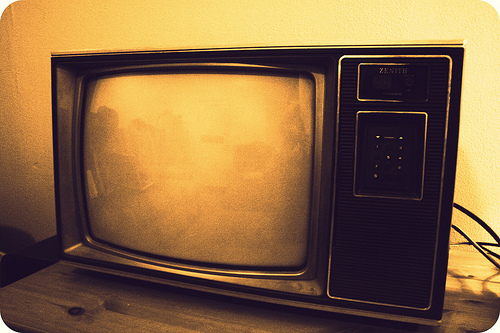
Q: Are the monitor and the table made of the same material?
A: No, the monitor is made of glass and the table is made of wood.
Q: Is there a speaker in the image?
A: Yes, there is a speaker.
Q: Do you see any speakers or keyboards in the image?
A: Yes, there is a speaker.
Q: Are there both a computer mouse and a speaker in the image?
A: No, there is a speaker but no computer mice.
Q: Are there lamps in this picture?
A: No, there are no lamps.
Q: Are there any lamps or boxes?
A: No, there are no lamps or boxes.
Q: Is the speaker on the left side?
A: No, the speaker is on the right of the image.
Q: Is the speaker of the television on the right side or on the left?
A: The speaker is on the right of the image.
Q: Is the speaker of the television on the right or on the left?
A: The speaker is on the right of the image.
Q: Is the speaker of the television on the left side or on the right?
A: The speaker is on the right of the image.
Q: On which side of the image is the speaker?
A: The speaker is on the right of the image.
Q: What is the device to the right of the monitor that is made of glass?
A: The device is a speaker.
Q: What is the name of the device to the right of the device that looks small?
A: The device is a speaker.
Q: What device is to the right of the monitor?
A: The device is a speaker.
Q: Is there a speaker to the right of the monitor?
A: Yes, there is a speaker to the right of the monitor.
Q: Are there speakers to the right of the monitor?
A: Yes, there is a speaker to the right of the monitor.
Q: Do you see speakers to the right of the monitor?
A: Yes, there is a speaker to the right of the monitor.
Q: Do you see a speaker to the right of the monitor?
A: Yes, there is a speaker to the right of the monitor.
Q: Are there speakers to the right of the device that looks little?
A: Yes, there is a speaker to the right of the monitor.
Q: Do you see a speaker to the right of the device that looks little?
A: Yes, there is a speaker to the right of the monitor.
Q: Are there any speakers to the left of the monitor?
A: No, the speaker is to the right of the monitor.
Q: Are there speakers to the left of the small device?
A: No, the speaker is to the right of the monitor.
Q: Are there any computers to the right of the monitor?
A: No, there is a speaker to the right of the monitor.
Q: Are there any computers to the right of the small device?
A: No, there is a speaker to the right of the monitor.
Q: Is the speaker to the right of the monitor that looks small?
A: Yes, the speaker is to the right of the monitor.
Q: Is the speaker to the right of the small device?
A: Yes, the speaker is to the right of the monitor.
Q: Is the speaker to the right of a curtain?
A: No, the speaker is to the right of the monitor.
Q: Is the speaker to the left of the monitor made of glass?
A: No, the speaker is to the right of the monitor.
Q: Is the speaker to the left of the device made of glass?
A: No, the speaker is to the right of the monitor.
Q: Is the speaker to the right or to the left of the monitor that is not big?
A: The speaker is to the right of the monitor.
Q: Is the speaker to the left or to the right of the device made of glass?
A: The speaker is to the right of the monitor.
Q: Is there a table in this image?
A: Yes, there is a table.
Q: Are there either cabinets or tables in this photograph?
A: Yes, there is a table.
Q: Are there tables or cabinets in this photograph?
A: Yes, there is a table.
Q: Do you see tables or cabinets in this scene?
A: Yes, there is a table.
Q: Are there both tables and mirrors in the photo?
A: No, there is a table but no mirrors.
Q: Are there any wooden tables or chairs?
A: Yes, there is a wood table.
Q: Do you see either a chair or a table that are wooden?
A: Yes, the table is wooden.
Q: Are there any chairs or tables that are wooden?
A: Yes, the table is wooden.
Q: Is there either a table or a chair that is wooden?
A: Yes, the table is wooden.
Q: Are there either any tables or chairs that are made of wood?
A: Yes, the table is made of wood.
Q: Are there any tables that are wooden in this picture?
A: Yes, there is a wood table.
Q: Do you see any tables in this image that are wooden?
A: Yes, there is a table that is wooden.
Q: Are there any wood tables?
A: Yes, there is a table that is made of wood.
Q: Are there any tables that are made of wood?
A: Yes, there is a table that is made of wood.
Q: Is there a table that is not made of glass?
A: Yes, there is a table that is made of wood.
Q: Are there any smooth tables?
A: Yes, there is a smooth table.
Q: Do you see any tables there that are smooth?
A: Yes, there is a table that is smooth.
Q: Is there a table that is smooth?
A: Yes, there is a table that is smooth.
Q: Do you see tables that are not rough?
A: Yes, there is a smooth table.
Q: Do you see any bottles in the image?
A: No, there are no bottles.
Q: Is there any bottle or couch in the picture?
A: No, there are no bottles or couches.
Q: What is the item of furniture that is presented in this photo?
A: The piece of furniture is a table.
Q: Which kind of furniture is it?
A: The piece of furniture is a table.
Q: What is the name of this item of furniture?
A: This is a table.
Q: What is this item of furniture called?
A: This is a table.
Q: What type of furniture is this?
A: This is a table.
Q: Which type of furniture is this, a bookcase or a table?
A: This is a table.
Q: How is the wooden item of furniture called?
A: The piece of furniture is a table.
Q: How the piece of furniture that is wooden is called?
A: The piece of furniture is a table.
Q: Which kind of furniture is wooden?
A: The furniture is a table.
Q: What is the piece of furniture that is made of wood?
A: The piece of furniture is a table.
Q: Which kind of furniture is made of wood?
A: The furniture is a table.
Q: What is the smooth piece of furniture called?
A: The piece of furniture is a table.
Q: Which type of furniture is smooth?
A: The furniture is a table.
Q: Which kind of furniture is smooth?
A: The furniture is a table.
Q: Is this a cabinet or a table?
A: This is a table.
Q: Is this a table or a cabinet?
A: This is a table.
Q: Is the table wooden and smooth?
A: Yes, the table is wooden and smooth.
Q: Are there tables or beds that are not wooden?
A: No, there is a table but it is wooden.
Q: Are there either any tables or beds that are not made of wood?
A: No, there is a table but it is made of wood.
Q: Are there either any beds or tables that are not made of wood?
A: No, there is a table but it is made of wood.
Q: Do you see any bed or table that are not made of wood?
A: No, there is a table but it is made of wood.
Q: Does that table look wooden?
A: Yes, the table is wooden.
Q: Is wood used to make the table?
A: Yes, the table is made of wood.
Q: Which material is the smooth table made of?
A: The table is made of wood.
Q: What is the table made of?
A: The table is made of wood.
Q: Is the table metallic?
A: No, the table is wooden.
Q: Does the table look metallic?
A: No, the table is wooden.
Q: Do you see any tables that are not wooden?
A: No, there is a table but it is wooden.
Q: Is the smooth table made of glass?
A: No, the table is made of wood.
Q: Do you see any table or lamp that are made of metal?
A: No, there is a table but it is made of wood.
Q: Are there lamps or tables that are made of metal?
A: No, there is a table but it is made of wood.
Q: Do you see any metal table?
A: No, there is a table but it is made of wood.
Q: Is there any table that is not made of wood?
A: No, there is a table but it is made of wood.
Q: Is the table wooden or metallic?
A: The table is wooden.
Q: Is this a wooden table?
A: Yes, this is a wooden table.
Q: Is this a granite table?
A: No, this is a wooden table.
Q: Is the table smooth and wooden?
A: Yes, the table is smooth and wooden.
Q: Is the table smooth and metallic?
A: No, the table is smooth but wooden.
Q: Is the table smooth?
A: Yes, the table is smooth.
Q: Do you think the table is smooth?
A: Yes, the table is smooth.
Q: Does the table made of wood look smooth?
A: Yes, the table is smooth.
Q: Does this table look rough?
A: No, the table is smooth.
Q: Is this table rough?
A: No, the table is smooth.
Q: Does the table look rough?
A: No, the table is smooth.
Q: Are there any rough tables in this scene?
A: No, there is a table but it is smooth.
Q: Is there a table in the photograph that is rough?
A: No, there is a table but it is smooth.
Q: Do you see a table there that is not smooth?
A: No, there is a table but it is smooth.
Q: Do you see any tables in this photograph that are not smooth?
A: No, there is a table but it is smooth.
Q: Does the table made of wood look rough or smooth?
A: The table is smooth.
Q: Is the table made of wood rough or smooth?
A: The table is smooth.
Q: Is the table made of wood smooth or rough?
A: The table is smooth.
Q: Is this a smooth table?
A: Yes, this is a smooth table.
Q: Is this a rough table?
A: No, this is a smooth table.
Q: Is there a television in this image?
A: Yes, there is a television.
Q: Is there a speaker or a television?
A: Yes, there is a television.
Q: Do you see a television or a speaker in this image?
A: Yes, there is a television.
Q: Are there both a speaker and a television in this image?
A: Yes, there are both a television and a speaker.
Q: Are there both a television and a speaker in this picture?
A: Yes, there are both a television and a speaker.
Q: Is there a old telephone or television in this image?
A: Yes, there is an old television.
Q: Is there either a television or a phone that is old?
A: Yes, the television is old.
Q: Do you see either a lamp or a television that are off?
A: Yes, the television is off.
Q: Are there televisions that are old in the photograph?
A: Yes, there is an old television.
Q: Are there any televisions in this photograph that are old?
A: Yes, there is a television that is old.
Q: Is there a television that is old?
A: Yes, there is a television that is old.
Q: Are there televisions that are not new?
A: Yes, there is a old television.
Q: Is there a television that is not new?
A: Yes, there is a old television.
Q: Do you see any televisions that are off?
A: Yes, there is a television that is off.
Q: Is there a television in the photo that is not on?
A: Yes, there is a television that is off.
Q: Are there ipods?
A: No, there are no ipods.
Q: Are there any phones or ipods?
A: No, there are no ipods or phones.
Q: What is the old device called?
A: The device is a television.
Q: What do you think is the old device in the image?
A: The device is a television.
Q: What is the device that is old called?
A: The device is a television.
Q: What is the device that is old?
A: The device is a television.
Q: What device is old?
A: The device is a television.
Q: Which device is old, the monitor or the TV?
A: The TV is old.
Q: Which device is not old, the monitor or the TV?
A: The monitor is not old.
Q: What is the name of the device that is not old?
A: The device is a monitor.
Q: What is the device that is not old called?
A: The device is a monitor.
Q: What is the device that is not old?
A: The device is a monitor.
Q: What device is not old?
A: The device is a monitor.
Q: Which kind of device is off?
A: The device is a television.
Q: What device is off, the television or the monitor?
A: The television is off.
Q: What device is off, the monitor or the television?
A: The television is off.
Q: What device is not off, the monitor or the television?
A: The monitor is not off.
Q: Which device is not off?
A: The device is a monitor.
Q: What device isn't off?
A: The device is a monitor.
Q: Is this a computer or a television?
A: This is a television.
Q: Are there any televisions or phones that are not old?
A: No, there is a television but it is old.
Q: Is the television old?
A: Yes, the television is old.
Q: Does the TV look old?
A: Yes, the TV is old.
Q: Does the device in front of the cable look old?
A: Yes, the TV is old.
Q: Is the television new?
A: No, the television is old.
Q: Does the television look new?
A: No, the television is old.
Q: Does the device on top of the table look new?
A: No, the television is old.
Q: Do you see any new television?
A: No, there is a television but it is old.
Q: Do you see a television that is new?
A: No, there is a television but it is old.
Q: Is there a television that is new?
A: No, there is a television but it is old.